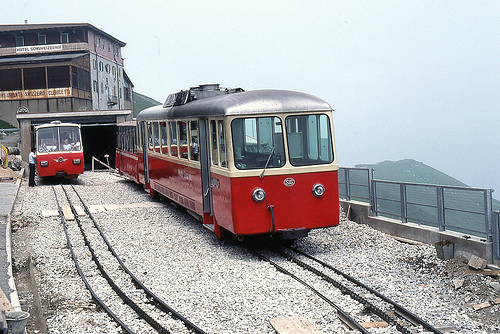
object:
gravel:
[30, 181, 456, 333]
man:
[28, 148, 37, 187]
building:
[0, 22, 134, 128]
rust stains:
[71, 98, 73, 111]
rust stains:
[56, 99, 59, 111]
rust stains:
[47, 99, 50, 112]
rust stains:
[86, 100, 88, 105]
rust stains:
[19, 100, 22, 106]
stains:
[78, 89, 79, 97]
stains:
[37, 99, 40, 106]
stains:
[26, 99, 29, 107]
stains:
[10, 101, 12, 104]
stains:
[84, 90, 86, 98]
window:
[319, 114, 330, 161]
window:
[286, 114, 334, 165]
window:
[190, 120, 201, 161]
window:
[38, 127, 59, 152]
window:
[132, 137, 135, 155]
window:
[211, 121, 218, 166]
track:
[50, 183, 205, 334]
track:
[238, 239, 437, 332]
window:
[217, 120, 228, 169]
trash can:
[435, 239, 454, 260]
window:
[160, 122, 169, 156]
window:
[168, 121, 177, 157]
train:
[115, 84, 340, 241]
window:
[231, 117, 285, 170]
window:
[147, 123, 153, 151]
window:
[258, 117, 274, 155]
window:
[60, 126, 81, 150]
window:
[243, 118, 258, 154]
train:
[34, 121, 84, 180]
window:
[136, 124, 141, 150]